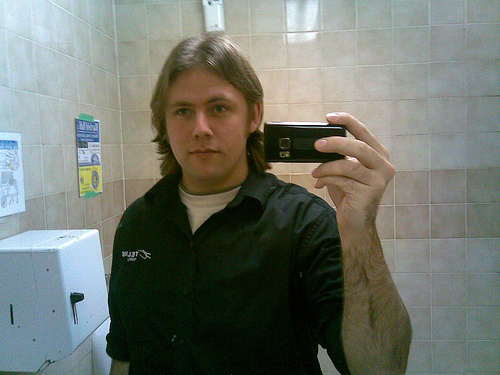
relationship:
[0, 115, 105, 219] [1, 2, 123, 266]
papers on wall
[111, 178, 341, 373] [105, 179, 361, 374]
tshirt under shirt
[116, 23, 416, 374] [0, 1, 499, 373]
man front mirror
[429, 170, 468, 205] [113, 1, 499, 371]
tile on wall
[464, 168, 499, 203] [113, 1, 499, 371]
tile on wall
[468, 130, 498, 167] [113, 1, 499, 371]
tile on wall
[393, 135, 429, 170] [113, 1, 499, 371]
tile on wall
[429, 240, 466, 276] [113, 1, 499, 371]
tile on wall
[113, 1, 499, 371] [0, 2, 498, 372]
wall in bathroom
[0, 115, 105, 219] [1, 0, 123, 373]
papers taped to wall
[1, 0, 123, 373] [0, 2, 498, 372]
wall in bathroom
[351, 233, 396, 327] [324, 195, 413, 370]
hair on arm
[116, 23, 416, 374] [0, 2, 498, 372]
man standing in bathroom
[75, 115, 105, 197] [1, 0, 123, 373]
paper hanging on wall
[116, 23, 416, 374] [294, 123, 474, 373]
man has arm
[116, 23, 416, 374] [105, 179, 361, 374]
man wearing shirt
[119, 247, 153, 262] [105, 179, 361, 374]
writing on shirt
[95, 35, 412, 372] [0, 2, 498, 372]
person in bathroom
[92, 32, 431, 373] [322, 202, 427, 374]
man has arm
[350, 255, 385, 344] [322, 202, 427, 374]
hair on arm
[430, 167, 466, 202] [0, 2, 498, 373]
tile on wall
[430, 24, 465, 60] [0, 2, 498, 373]
tile on wall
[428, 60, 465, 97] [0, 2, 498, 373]
tile on wall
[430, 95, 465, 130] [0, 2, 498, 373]
tile on wall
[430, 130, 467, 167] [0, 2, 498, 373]
tile on wall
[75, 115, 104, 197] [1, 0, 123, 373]
paper taped to wall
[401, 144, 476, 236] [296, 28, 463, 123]
tiles on walls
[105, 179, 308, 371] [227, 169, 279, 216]
shirt with collar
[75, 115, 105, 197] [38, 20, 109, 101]
paper taped to wall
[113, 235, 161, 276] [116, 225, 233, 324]
logo on black shirt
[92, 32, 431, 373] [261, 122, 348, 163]
man holding cell phone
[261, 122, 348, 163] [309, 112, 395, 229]
cell phone with hand